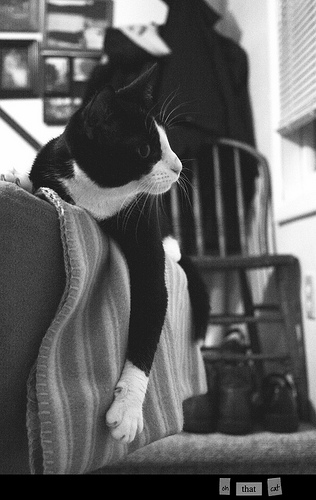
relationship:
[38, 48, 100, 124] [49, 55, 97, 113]
picture of family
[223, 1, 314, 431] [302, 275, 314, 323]
wall has a socket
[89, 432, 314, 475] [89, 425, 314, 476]
carpet has brown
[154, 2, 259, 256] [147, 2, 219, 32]
coat on a coat hanger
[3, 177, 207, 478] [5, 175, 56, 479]
couch has a armrest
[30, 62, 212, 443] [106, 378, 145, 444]
cat has paws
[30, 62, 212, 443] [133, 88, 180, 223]
cat has whiskers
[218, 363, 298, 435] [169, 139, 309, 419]
shoes are under a chair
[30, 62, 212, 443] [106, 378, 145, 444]
cat has a paws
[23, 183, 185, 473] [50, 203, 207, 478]
towell has lines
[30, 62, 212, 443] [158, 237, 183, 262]
cat has a leg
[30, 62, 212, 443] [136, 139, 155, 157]
cat has an eye